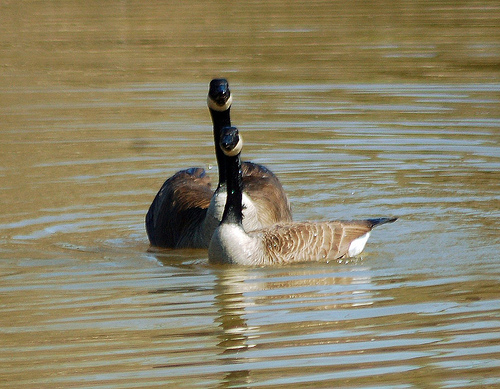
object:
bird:
[144, 78, 295, 250]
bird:
[206, 127, 399, 265]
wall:
[390, 136, 444, 191]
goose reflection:
[211, 266, 248, 387]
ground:
[376, 109, 449, 151]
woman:
[367, 206, 401, 233]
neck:
[213, 120, 235, 178]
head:
[207, 77, 232, 114]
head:
[218, 126, 245, 157]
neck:
[221, 158, 246, 225]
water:
[258, 24, 430, 131]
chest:
[206, 222, 253, 266]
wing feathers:
[313, 238, 348, 266]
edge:
[335, 220, 360, 255]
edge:
[347, 219, 358, 260]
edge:
[316, 219, 324, 258]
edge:
[313, 220, 319, 250]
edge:
[299, 219, 307, 246]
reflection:
[72, 70, 198, 107]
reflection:
[297, 80, 476, 100]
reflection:
[412, 223, 489, 277]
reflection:
[65, 310, 253, 366]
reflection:
[338, 315, 453, 369]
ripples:
[288, 278, 391, 351]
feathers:
[284, 219, 303, 233]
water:
[14, 11, 145, 94]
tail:
[367, 215, 400, 228]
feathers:
[283, 240, 316, 260]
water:
[403, 276, 481, 322]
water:
[300, 108, 462, 262]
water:
[193, 29, 249, 73]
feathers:
[233, 238, 259, 257]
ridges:
[0, 192, 499, 388]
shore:
[0, 0, 499, 387]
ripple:
[283, 143, 499, 267]